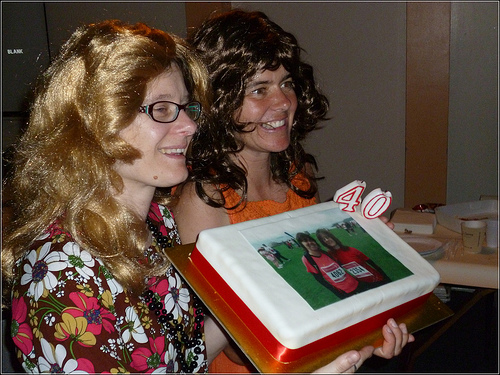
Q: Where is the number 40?
A: On the cake.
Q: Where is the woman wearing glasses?
A: Closest to the camera.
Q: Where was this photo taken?
A: In a kitchen.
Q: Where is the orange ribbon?
A: Around the bottom of the cake.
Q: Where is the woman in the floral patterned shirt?
A: On the left.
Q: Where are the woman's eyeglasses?
A: On face.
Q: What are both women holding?
A: Cake.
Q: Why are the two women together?
A: Best friends.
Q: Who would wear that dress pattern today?
A: No fashion conscious individual.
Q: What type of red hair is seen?
A: Red wig.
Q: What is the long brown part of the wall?
A: Partition.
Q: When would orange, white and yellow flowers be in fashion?
A: No time soon.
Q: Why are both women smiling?
A: For good picture.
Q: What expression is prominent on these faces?
A: Happiness.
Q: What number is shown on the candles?
A: 40.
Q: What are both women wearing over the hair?
A: Wigs.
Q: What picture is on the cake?
A: Two women.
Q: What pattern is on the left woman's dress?
A: Flowers.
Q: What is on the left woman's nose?
A: Glasses.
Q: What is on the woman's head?
A: Wig.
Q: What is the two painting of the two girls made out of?
A: Frosting.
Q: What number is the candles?
A: 40.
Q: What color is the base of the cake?
A: Red.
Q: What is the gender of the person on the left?
A: Female.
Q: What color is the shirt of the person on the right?
A: Orange.